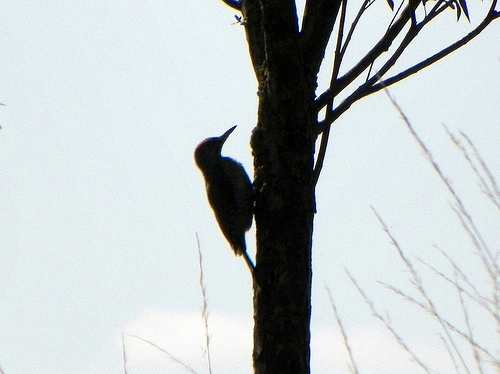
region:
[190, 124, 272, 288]
A bird on a tree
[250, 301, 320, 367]
A stem of a tree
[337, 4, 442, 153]
A branch of a tree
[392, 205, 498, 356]
Grass growing with a tree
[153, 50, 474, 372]
Tree growing with a tree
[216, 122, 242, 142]
A beak of a bird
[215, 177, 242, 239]
Black wings of a bird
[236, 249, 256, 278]
A featherely tail of a bird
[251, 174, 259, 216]
A bird's feet holding into a tree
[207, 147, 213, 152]
A small eye of a bird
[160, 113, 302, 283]
black crow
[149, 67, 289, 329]
black woodpecker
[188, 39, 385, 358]
black bird on tree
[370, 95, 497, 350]
tree with no leaves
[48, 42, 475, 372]
blue sky in the background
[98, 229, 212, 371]
white clouds in the blue sky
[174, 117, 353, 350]
bird standing on tree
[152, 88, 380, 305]
black bird perched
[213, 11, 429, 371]
sillouette of bird on tree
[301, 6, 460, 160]
sillouette of branches, tree and bird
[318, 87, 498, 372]
some bare tree braches in the background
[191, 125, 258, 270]
a little bird hanging on the tree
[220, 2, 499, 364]
the tree the bird is sitting on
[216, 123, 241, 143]
the beak of the little bird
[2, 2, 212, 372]
the bright blue sky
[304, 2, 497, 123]
the almost bare tree braches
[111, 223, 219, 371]
some more tree branches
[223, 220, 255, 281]
the tail of the bird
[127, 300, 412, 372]
a cloud in the sky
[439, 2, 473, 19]
a few little leaves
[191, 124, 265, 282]
a bird perched on a tree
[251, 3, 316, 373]
a small tree trunk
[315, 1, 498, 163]
small branches off of a tree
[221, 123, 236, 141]
beak of a bird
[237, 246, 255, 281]
the leg of a bird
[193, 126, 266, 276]
small bird on a tree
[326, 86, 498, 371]
wisps of grass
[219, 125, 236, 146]
a beak of a small bird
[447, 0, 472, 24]
leaves on a branch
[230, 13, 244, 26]
small leaf on a tree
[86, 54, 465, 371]
picture taken outdoors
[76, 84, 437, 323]
picture taken during the day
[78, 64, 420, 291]
picture taken outside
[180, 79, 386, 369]
a bird on a tree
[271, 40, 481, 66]
the tree has branches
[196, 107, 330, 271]
a bird is holding onto the tree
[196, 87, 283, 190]
the bird has a pointy beak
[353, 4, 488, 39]
the few leaves are visible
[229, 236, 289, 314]
the tail of the bird is against the tree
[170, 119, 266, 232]
the bird is on the left side